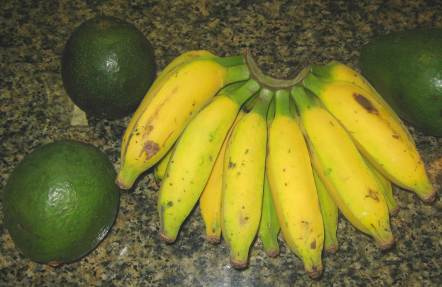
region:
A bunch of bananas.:
[161, 49, 399, 226]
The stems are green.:
[213, 51, 272, 100]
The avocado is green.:
[5, 130, 126, 273]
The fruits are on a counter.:
[117, 224, 194, 285]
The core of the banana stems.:
[225, 37, 310, 88]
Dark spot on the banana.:
[346, 84, 393, 116]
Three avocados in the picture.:
[37, 8, 436, 263]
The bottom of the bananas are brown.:
[228, 251, 327, 278]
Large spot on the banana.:
[131, 120, 164, 178]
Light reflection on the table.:
[53, 94, 107, 144]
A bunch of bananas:
[168, 32, 382, 285]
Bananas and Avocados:
[2, 0, 440, 255]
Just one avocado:
[0, 119, 162, 283]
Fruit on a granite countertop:
[4, 1, 440, 284]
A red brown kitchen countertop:
[4, 1, 438, 235]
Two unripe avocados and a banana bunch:
[5, 3, 263, 283]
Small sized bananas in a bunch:
[176, 27, 375, 285]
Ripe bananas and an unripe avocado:
[281, 17, 438, 193]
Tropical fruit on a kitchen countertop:
[5, 3, 440, 268]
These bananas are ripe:
[176, 25, 358, 285]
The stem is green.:
[223, 57, 276, 101]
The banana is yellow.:
[228, 114, 311, 226]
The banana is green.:
[250, 199, 282, 248]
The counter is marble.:
[131, 231, 237, 284]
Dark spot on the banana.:
[127, 118, 176, 174]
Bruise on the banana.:
[345, 92, 391, 129]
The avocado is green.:
[0, 140, 141, 279]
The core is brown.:
[232, 27, 326, 102]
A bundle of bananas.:
[140, 50, 421, 241]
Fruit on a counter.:
[0, 21, 441, 272]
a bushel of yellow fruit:
[115, 45, 435, 269]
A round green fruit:
[0, 130, 115, 259]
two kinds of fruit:
[6, 5, 430, 275]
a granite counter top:
[0, 6, 52, 123]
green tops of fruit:
[206, 35, 335, 113]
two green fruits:
[0, 8, 154, 261]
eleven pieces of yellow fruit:
[110, 43, 434, 271]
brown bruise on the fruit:
[346, 85, 388, 128]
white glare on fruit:
[25, 171, 87, 220]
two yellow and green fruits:
[300, 57, 439, 240]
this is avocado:
[4, 158, 112, 236]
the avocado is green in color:
[36, 180, 80, 222]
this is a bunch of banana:
[170, 65, 352, 227]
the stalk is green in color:
[237, 85, 249, 94]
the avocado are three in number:
[21, 39, 441, 227]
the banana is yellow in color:
[149, 106, 175, 126]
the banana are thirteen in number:
[155, 73, 362, 211]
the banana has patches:
[47, 198, 69, 226]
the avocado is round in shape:
[18, 161, 102, 214]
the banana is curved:
[159, 83, 212, 97]